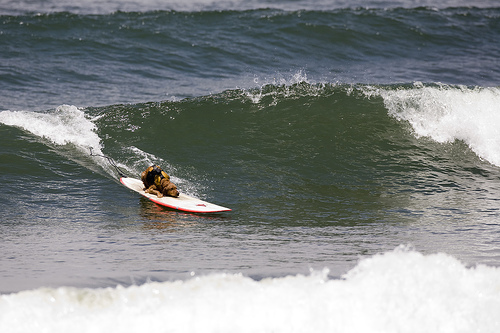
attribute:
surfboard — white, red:
[119, 175, 234, 216]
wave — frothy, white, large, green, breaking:
[3, 80, 499, 198]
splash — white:
[1, 251, 500, 324]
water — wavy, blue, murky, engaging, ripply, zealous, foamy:
[3, 2, 499, 263]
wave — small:
[4, 2, 500, 82]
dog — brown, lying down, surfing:
[140, 159, 179, 200]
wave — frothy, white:
[1, 252, 499, 331]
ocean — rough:
[2, 2, 497, 288]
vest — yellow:
[148, 167, 169, 184]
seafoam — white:
[387, 86, 499, 168]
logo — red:
[196, 201, 207, 209]